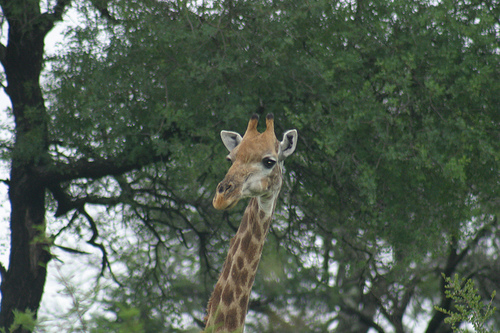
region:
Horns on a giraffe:
[241, 113, 275, 130]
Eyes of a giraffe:
[219, 149, 278, 169]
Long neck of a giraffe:
[202, 202, 271, 318]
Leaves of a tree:
[338, 44, 471, 173]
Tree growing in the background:
[345, 38, 472, 242]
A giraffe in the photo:
[164, 122, 334, 330]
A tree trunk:
[5, 57, 90, 323]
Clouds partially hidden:
[58, 12, 135, 73]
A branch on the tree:
[57, 133, 148, 190]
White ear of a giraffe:
[205, 127, 312, 160]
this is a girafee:
[153, 109, 313, 331]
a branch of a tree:
[48, 180, 140, 315]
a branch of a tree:
[255, 210, 430, 328]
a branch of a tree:
[39, 30, 179, 125]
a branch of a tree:
[379, 109, 494, 226]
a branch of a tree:
[95, 6, 222, 105]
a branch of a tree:
[175, 25, 353, 95]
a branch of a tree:
[379, 18, 456, 140]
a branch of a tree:
[105, 185, 225, 307]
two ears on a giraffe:
[219, 126, 299, 153]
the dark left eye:
[263, 155, 274, 172]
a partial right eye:
[225, 157, 234, 164]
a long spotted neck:
[203, 199, 265, 330]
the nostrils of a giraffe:
[215, 185, 237, 195]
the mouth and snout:
[212, 180, 242, 213]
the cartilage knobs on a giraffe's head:
[245, 115, 273, 133]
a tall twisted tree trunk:
[0, 0, 56, 331]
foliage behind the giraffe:
[3, 0, 499, 327]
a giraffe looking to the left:
[203, 111, 299, 331]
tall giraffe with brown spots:
[196, 100, 301, 332]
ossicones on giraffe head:
[244, 108, 280, 134]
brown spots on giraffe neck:
[234, 253, 256, 301]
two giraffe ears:
[211, 120, 303, 160]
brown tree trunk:
[0, 0, 68, 332]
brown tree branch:
[49, 134, 166, 196]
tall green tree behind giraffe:
[0, 1, 499, 331]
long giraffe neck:
[196, 198, 279, 328]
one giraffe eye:
[256, 150, 281, 175]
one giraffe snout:
[205, 175, 245, 212]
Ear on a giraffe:
[211, 124, 247, 157]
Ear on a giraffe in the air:
[271, 129, 307, 161]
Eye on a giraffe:
[259, 152, 275, 172]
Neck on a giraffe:
[194, 185, 274, 331]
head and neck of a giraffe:
[197, 106, 307, 331]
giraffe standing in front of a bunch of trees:
[0, 0, 495, 332]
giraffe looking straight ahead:
[199, 108, 304, 331]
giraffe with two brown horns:
[205, 106, 299, 331]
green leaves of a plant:
[427, 266, 499, 330]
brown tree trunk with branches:
[1, 0, 166, 332]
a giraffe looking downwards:
[202, 108, 297, 331]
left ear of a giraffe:
[281, 128, 296, 158]